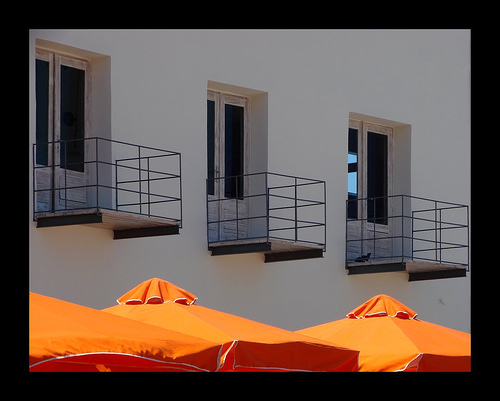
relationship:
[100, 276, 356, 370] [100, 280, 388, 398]
orange tent on umbrella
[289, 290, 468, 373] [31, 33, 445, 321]
orange tent near house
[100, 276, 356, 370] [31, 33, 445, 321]
orange tent near house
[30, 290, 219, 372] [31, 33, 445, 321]
tent near house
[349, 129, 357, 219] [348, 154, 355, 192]
window has light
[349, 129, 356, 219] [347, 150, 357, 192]
window has light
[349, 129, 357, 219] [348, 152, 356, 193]
window has light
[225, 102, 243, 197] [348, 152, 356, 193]
window has light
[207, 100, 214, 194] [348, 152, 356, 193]
window has light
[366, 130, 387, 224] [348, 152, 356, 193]
window has light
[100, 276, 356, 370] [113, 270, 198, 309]
orange tent has top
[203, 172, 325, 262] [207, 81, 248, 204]
balcony of room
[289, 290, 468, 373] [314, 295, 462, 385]
orange tent on umbrella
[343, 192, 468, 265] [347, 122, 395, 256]
balcony has doors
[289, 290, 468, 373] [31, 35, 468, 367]
orange tent on outdoor area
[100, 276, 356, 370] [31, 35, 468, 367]
orange tent on outdoor area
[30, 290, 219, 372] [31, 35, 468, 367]
tent on outdoor area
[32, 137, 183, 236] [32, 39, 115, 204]
balconies of rooms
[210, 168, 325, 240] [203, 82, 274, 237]
balcony of rooms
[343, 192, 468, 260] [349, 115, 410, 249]
balcony of rooms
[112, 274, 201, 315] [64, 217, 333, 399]
orange tent with umbrella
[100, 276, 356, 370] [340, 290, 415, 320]
orange tent with orange tent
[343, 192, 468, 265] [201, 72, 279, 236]
balcony by apartment doors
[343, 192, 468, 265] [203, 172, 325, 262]
balcony by balcony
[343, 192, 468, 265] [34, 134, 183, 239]
balcony by balcony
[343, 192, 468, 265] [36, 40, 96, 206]
balcony by doors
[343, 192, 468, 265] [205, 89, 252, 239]
balcony by doors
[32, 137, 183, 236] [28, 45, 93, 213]
balconies by doors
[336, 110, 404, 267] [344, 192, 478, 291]
doors from balcony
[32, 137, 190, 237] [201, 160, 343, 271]
balconies of an balconies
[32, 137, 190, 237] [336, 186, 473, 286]
balconies of an balconies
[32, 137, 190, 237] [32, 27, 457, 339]
balconies of an house